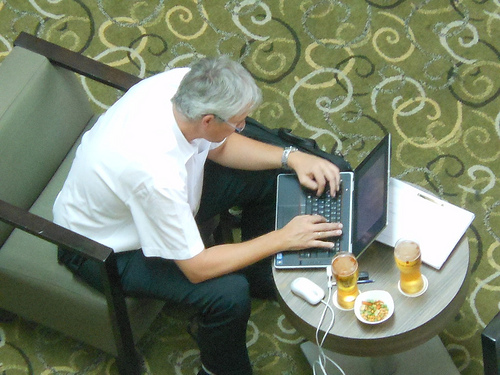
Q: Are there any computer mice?
A: Yes, there is a computer mouse.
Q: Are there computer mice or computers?
A: Yes, there is a computer mouse.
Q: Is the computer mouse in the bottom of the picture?
A: Yes, the computer mouse is in the bottom of the image.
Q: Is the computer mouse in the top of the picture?
A: No, the computer mouse is in the bottom of the image.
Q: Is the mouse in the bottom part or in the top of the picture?
A: The mouse is in the bottom of the image.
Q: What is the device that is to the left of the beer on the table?
A: The device is a computer mouse.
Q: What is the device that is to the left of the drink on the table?
A: The device is a computer mouse.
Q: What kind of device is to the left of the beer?
A: The device is a computer mouse.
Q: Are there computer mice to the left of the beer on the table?
A: Yes, there is a computer mouse to the left of the beer.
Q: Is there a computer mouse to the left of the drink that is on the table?
A: Yes, there is a computer mouse to the left of the beer.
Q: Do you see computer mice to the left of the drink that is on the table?
A: Yes, there is a computer mouse to the left of the beer.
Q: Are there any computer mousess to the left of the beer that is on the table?
A: No, there is a computer mouse to the left of the beer.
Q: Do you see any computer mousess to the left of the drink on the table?
A: No, there is a computer mouse to the left of the beer.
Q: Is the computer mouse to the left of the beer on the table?
A: Yes, the computer mouse is to the left of the beer.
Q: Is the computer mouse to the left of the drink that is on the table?
A: Yes, the computer mouse is to the left of the beer.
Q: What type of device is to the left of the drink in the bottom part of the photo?
A: The device is a computer mouse.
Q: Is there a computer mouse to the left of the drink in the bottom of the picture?
A: Yes, there is a computer mouse to the left of the drink.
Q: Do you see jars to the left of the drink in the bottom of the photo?
A: No, there is a computer mouse to the left of the drink.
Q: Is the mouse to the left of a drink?
A: Yes, the mouse is to the left of a drink.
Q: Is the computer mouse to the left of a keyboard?
A: No, the computer mouse is to the left of a drink.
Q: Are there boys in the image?
A: No, there are no boys.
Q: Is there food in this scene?
A: Yes, there is food.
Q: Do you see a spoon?
A: No, there are no spoons.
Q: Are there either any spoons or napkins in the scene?
A: No, there are no spoons or napkins.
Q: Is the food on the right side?
A: Yes, the food is on the right of the image.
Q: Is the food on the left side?
A: No, the food is on the right of the image.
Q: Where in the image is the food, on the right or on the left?
A: The food is on the right of the image.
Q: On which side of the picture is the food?
A: The food is on the right of the image.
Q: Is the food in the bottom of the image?
A: Yes, the food is in the bottom of the image.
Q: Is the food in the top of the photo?
A: No, the food is in the bottom of the image.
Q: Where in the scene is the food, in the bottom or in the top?
A: The food is in the bottom of the image.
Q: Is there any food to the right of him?
A: Yes, there is food to the right of the man.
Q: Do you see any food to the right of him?
A: Yes, there is food to the right of the man.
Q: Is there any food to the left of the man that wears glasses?
A: No, the food is to the right of the man.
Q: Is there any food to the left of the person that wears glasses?
A: No, the food is to the right of the man.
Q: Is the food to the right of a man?
A: Yes, the food is to the right of a man.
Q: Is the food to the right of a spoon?
A: No, the food is to the right of a man.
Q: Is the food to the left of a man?
A: No, the food is to the right of a man.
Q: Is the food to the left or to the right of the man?
A: The food is to the right of the man.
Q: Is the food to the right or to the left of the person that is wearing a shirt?
A: The food is to the right of the man.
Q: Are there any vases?
A: No, there are no vases.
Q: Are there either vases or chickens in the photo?
A: No, there are no vases or chickens.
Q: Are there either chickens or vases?
A: No, there are no vases or chickens.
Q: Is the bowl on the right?
A: Yes, the bowl is on the right of the image.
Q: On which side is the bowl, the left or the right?
A: The bowl is on the right of the image.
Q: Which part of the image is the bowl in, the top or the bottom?
A: The bowl is in the bottom of the image.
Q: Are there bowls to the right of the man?
A: Yes, there is a bowl to the right of the man.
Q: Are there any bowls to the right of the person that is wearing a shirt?
A: Yes, there is a bowl to the right of the man.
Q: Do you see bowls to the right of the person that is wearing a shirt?
A: Yes, there is a bowl to the right of the man.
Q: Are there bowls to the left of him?
A: No, the bowl is to the right of the man.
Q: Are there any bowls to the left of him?
A: No, the bowl is to the right of the man.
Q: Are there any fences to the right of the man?
A: No, there is a bowl to the right of the man.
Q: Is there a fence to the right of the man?
A: No, there is a bowl to the right of the man.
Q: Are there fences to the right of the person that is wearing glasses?
A: No, there is a bowl to the right of the man.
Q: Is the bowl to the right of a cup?
A: No, the bowl is to the right of the man.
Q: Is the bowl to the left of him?
A: No, the bowl is to the right of the man.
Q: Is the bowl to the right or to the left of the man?
A: The bowl is to the right of the man.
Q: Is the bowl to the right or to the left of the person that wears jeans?
A: The bowl is to the right of the man.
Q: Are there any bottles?
A: No, there are no bottles.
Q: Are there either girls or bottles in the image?
A: No, there are no bottles or girls.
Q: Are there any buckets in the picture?
A: No, there are no buckets.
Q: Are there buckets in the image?
A: No, there are no buckets.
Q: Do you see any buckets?
A: No, there are no buckets.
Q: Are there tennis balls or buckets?
A: No, there are no buckets or tennis balls.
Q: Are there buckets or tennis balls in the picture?
A: No, there are no buckets or tennis balls.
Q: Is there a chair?
A: Yes, there is a chair.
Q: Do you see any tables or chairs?
A: Yes, there is a chair.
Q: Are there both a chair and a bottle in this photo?
A: No, there is a chair but no bottles.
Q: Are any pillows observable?
A: No, there are no pillows.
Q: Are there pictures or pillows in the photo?
A: No, there are no pillows or pictures.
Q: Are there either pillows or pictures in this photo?
A: No, there are no pillows or pictures.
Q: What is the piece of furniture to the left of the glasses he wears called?
A: The piece of furniture is a chair.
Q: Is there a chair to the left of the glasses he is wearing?
A: Yes, there is a chair to the left of the glasses.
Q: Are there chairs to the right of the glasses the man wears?
A: No, the chair is to the left of the glasses.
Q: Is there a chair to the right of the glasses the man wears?
A: No, the chair is to the left of the glasses.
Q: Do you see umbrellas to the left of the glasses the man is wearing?
A: No, there is a chair to the left of the glasses.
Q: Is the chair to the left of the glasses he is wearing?
A: Yes, the chair is to the left of the glasses.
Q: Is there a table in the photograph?
A: Yes, there is a table.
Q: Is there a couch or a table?
A: Yes, there is a table.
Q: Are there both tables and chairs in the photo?
A: Yes, there are both a table and a chair.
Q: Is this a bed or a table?
A: This is a table.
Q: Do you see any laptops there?
A: Yes, there is a laptop.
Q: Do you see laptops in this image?
A: Yes, there is a laptop.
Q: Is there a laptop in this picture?
A: Yes, there is a laptop.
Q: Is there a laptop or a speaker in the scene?
A: Yes, there is a laptop.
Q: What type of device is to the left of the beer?
A: The device is a laptop.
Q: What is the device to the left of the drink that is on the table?
A: The device is a laptop.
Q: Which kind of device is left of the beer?
A: The device is a laptop.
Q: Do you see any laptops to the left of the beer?
A: Yes, there is a laptop to the left of the beer.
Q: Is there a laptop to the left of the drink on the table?
A: Yes, there is a laptop to the left of the beer.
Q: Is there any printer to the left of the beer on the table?
A: No, there is a laptop to the left of the beer.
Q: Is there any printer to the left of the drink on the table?
A: No, there is a laptop to the left of the beer.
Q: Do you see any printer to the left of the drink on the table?
A: No, there is a laptop to the left of the beer.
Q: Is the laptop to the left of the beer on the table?
A: Yes, the laptop is to the left of the beer.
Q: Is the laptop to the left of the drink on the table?
A: Yes, the laptop is to the left of the beer.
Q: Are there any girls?
A: No, there are no girls.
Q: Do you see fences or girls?
A: No, there are no girls or fences.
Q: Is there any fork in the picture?
A: No, there are no forks.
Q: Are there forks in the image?
A: No, there are no forks.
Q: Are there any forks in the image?
A: No, there are no forks.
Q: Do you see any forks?
A: No, there are no forks.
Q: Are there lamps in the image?
A: No, there are no lamps.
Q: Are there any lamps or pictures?
A: No, there are no lamps or pictures.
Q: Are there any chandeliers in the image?
A: No, there are no chandeliers.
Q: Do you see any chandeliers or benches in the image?
A: No, there are no chandeliers or benches.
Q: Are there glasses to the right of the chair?
A: Yes, there are glasses to the right of the chair.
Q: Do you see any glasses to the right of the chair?
A: Yes, there are glasses to the right of the chair.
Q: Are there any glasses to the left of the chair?
A: No, the glasses are to the right of the chair.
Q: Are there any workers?
A: No, there are no workers.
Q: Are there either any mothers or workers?
A: No, there are no workers or mothers.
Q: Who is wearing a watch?
A: The man is wearing a watch.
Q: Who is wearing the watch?
A: The man is wearing a watch.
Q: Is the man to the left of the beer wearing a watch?
A: Yes, the man is wearing a watch.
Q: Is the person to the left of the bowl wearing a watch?
A: Yes, the man is wearing a watch.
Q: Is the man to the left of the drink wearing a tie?
A: No, the man is wearing a watch.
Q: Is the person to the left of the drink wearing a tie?
A: No, the man is wearing a watch.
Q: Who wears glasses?
A: The man wears glasses.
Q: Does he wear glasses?
A: Yes, the man wears glasses.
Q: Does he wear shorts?
A: No, the man wears glasses.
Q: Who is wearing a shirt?
A: The man is wearing a shirt.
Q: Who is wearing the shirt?
A: The man is wearing a shirt.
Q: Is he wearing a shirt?
A: Yes, the man is wearing a shirt.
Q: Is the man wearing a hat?
A: No, the man is wearing a shirt.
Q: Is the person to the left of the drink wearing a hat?
A: No, the man is wearing a shirt.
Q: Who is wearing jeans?
A: The man is wearing jeans.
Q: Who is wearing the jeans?
A: The man is wearing jeans.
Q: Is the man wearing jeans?
A: Yes, the man is wearing jeans.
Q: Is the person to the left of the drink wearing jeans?
A: Yes, the man is wearing jeans.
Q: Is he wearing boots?
A: No, the man is wearing jeans.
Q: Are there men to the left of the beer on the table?
A: Yes, there is a man to the left of the beer.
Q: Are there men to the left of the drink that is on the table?
A: Yes, there is a man to the left of the beer.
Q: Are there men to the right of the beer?
A: No, the man is to the left of the beer.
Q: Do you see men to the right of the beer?
A: No, the man is to the left of the beer.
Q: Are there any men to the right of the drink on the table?
A: No, the man is to the left of the beer.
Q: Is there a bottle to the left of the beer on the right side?
A: No, there is a man to the left of the beer.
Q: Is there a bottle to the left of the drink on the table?
A: No, there is a man to the left of the beer.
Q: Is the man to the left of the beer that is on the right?
A: Yes, the man is to the left of the beer.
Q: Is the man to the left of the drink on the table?
A: Yes, the man is to the left of the beer.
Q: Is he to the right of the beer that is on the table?
A: No, the man is to the left of the beer.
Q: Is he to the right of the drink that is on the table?
A: No, the man is to the left of the beer.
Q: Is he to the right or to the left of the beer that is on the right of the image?
A: The man is to the left of the beer.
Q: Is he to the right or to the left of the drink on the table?
A: The man is to the left of the beer.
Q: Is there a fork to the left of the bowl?
A: No, there is a man to the left of the bowl.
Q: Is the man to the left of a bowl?
A: Yes, the man is to the left of a bowl.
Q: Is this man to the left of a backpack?
A: No, the man is to the left of a bowl.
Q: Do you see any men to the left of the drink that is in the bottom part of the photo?
A: Yes, there is a man to the left of the drink.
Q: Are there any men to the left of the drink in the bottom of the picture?
A: Yes, there is a man to the left of the drink.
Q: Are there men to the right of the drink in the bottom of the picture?
A: No, the man is to the left of the drink.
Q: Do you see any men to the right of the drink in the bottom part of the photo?
A: No, the man is to the left of the drink.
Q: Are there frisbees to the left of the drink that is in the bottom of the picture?
A: No, there is a man to the left of the drink.